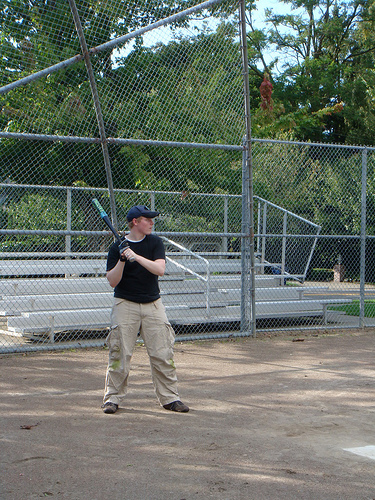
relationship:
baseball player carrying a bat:
[101, 203, 190, 417] [88, 194, 135, 262]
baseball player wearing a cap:
[101, 203, 190, 417] [124, 205, 160, 220]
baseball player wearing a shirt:
[101, 203, 190, 417] [106, 235, 167, 306]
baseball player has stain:
[101, 207, 191, 420] [108, 355, 124, 370]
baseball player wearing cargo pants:
[101, 203, 190, 417] [102, 298, 180, 407]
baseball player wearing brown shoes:
[101, 203, 190, 417] [99, 398, 193, 411]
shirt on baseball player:
[110, 235, 180, 286] [101, 203, 190, 417]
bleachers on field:
[20, 221, 304, 344] [80, 330, 373, 467]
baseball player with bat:
[101, 203, 190, 417] [67, 186, 137, 249]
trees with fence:
[217, 72, 368, 277] [108, 83, 339, 346]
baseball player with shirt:
[101, 203, 190, 417] [114, 241, 199, 271]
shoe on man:
[91, 383, 135, 411] [57, 195, 228, 434]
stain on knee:
[104, 349, 127, 368] [80, 338, 142, 374]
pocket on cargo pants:
[145, 295, 175, 320] [102, 298, 180, 407]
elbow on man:
[100, 257, 148, 297] [91, 204, 231, 402]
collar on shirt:
[116, 235, 148, 253] [104, 231, 189, 290]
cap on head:
[124, 207, 174, 225] [128, 201, 158, 251]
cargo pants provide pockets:
[110, 301, 181, 407] [165, 319, 177, 346]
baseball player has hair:
[101, 203, 190, 417] [124, 220, 132, 227]